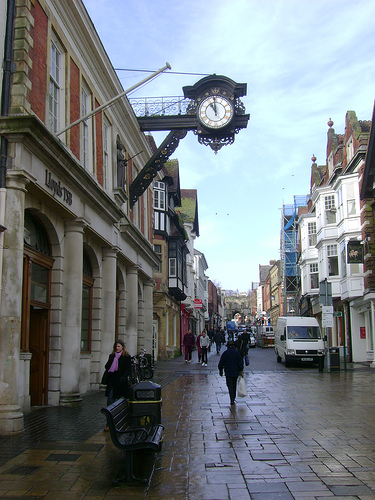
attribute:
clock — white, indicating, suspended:
[182, 73, 252, 153]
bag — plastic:
[237, 376, 251, 397]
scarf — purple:
[104, 349, 126, 372]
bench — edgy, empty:
[104, 395, 164, 487]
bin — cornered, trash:
[126, 380, 165, 425]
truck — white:
[273, 313, 325, 370]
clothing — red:
[182, 332, 197, 361]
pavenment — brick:
[2, 331, 374, 493]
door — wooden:
[29, 308, 53, 410]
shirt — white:
[199, 334, 209, 351]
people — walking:
[180, 319, 263, 407]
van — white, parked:
[274, 313, 327, 370]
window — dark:
[112, 153, 131, 194]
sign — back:
[317, 308, 337, 332]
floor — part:
[290, 391, 362, 465]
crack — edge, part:
[203, 461, 230, 469]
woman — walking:
[100, 336, 130, 402]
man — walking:
[182, 328, 196, 363]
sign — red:
[358, 326, 367, 339]